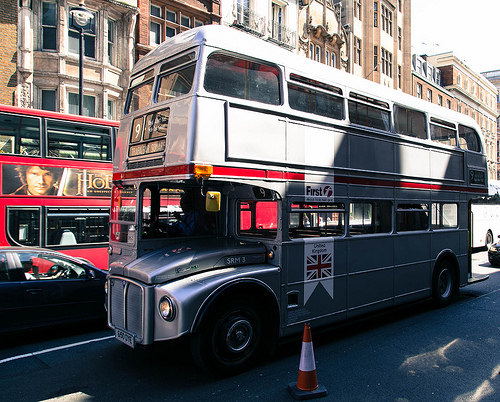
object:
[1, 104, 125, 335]
bus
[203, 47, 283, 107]
top window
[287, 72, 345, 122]
top window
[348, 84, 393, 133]
top window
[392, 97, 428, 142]
top window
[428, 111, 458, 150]
top window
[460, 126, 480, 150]
window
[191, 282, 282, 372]
wheel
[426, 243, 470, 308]
wheel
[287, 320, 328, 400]
cone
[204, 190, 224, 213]
mirror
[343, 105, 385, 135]
ground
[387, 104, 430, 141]
small window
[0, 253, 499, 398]
road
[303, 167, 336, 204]
poster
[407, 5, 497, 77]
sky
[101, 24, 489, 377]
bus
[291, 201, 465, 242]
windows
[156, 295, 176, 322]
headlamp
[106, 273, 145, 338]
grill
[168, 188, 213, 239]
driver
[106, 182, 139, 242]
windshield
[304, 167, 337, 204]
sign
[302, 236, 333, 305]
flag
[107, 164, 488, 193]
stripe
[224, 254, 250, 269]
number